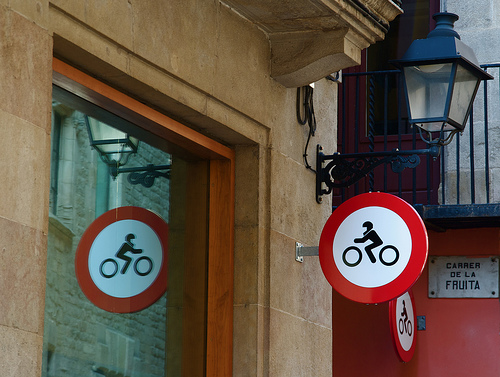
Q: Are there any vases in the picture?
A: No, there are no vases.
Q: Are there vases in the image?
A: No, there are no vases.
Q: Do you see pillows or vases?
A: No, there are no vases or pillows.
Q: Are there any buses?
A: No, there are no buses.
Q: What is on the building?
A: The sign is on the building.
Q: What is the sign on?
A: The sign is on the building.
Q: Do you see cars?
A: No, there are no cars.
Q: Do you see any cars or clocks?
A: No, there are no cars or clocks.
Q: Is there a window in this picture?
A: Yes, there is a window.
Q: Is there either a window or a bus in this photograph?
A: Yes, there is a window.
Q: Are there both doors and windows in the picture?
A: Yes, there are both a window and a door.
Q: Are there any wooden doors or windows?
A: Yes, there is a wood window.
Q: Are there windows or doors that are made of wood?
A: Yes, the window is made of wood.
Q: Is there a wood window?
A: Yes, there is a window that is made of wood.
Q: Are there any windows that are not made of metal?
A: Yes, there is a window that is made of wood.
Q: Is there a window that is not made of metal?
A: Yes, there is a window that is made of wood.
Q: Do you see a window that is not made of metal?
A: Yes, there is a window that is made of wood.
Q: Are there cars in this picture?
A: No, there are no cars.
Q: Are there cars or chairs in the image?
A: No, there are no cars or chairs.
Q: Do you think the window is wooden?
A: Yes, the window is wooden.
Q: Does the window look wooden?
A: Yes, the window is wooden.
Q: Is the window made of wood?
A: Yes, the window is made of wood.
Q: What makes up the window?
A: The window is made of wood.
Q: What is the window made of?
A: The window is made of wood.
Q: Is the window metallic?
A: No, the window is wooden.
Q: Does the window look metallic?
A: No, the window is wooden.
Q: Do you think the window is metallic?
A: No, the window is wooden.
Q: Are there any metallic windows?
A: No, there is a window but it is wooden.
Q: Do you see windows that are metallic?
A: No, there is a window but it is wooden.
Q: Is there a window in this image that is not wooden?
A: No, there is a window but it is wooden.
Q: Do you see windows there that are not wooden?
A: No, there is a window but it is wooden.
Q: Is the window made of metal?
A: No, the window is made of wood.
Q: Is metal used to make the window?
A: No, the window is made of wood.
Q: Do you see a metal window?
A: No, there is a window but it is made of wood.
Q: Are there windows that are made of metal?
A: No, there is a window but it is made of wood.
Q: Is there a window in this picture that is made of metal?
A: No, there is a window but it is made of wood.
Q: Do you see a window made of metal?
A: No, there is a window but it is made of wood.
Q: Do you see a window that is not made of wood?
A: No, there is a window but it is made of wood.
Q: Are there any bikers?
A: Yes, there is a biker.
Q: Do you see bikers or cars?
A: Yes, there is a biker.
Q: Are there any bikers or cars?
A: Yes, there is a biker.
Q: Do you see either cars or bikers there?
A: Yes, there is a biker.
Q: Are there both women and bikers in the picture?
A: No, there is a biker but no women.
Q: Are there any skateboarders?
A: No, there are no skateboarders.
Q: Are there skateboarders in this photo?
A: No, there are no skateboarders.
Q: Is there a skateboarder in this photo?
A: No, there are no skateboarders.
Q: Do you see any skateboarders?
A: No, there are no skateboarders.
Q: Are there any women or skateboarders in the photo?
A: No, there are no skateboarders or women.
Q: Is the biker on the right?
A: Yes, the biker is on the right of the image.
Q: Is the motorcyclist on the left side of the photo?
A: No, the motorcyclist is on the right of the image.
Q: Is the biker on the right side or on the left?
A: The biker is on the right of the image.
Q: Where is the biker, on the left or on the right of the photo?
A: The biker is on the right of the image.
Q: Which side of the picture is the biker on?
A: The biker is on the right of the image.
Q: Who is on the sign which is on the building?
A: The biker is on the sign.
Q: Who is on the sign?
A: The biker is on the sign.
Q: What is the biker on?
A: The biker is on the sign.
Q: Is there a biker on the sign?
A: Yes, there is a biker on the sign.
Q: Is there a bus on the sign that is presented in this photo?
A: No, there is a biker on the sign.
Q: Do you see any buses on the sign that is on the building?
A: No, there is a biker on the sign.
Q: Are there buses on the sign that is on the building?
A: No, there is a biker on the sign.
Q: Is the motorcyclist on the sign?
A: Yes, the motorcyclist is on the sign.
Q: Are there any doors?
A: Yes, there is a door.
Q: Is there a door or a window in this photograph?
A: Yes, there is a door.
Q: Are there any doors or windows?
A: Yes, there is a door.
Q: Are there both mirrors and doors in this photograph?
A: No, there is a door but no mirrors.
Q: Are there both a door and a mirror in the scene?
A: No, there is a door but no mirrors.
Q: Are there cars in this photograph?
A: No, there are no cars.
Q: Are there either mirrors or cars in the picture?
A: No, there are no cars or mirrors.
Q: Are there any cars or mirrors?
A: No, there are no cars or mirrors.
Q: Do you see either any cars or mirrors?
A: No, there are no cars or mirrors.